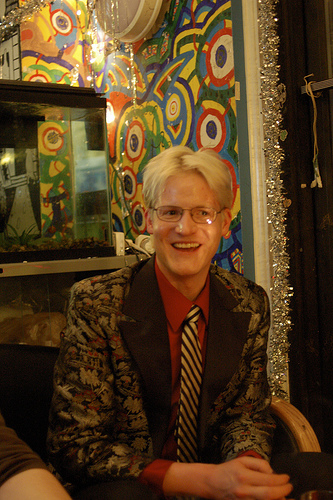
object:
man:
[47, 146, 293, 500]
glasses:
[146, 204, 228, 223]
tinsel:
[303, 72, 322, 189]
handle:
[300, 74, 333, 96]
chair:
[270, 395, 323, 500]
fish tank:
[0, 77, 118, 259]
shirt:
[138, 255, 265, 500]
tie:
[175, 304, 202, 465]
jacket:
[47, 251, 275, 500]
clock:
[96, 0, 169, 44]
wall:
[20, 0, 244, 276]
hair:
[141, 145, 234, 220]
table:
[0, 253, 148, 279]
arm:
[0, 413, 70, 500]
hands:
[220, 455, 294, 499]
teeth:
[174, 243, 199, 248]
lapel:
[199, 275, 252, 442]